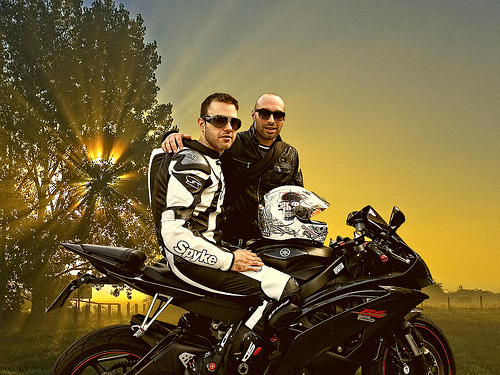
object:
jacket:
[138, 133, 241, 274]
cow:
[452, 292, 475, 309]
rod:
[443, 295, 453, 311]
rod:
[474, 293, 488, 312]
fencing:
[418, 292, 499, 313]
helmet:
[248, 178, 336, 254]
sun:
[62, 139, 143, 216]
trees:
[450, 277, 499, 296]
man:
[149, 81, 317, 288]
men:
[136, 83, 327, 375]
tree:
[3, 0, 188, 323]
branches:
[23, 156, 58, 218]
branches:
[7, 48, 44, 123]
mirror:
[381, 202, 412, 235]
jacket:
[156, 118, 310, 246]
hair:
[192, 89, 241, 123]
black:
[234, 221, 249, 233]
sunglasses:
[248, 104, 289, 122]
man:
[135, 88, 308, 375]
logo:
[347, 304, 389, 326]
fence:
[61, 294, 161, 331]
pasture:
[6, 320, 56, 363]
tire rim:
[355, 309, 460, 375]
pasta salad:
[31, 200, 458, 374]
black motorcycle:
[35, 198, 467, 374]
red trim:
[357, 310, 461, 374]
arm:
[147, 155, 230, 274]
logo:
[277, 246, 294, 261]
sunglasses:
[195, 109, 246, 135]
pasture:
[460, 303, 498, 372]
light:
[384, 204, 408, 233]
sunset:
[3, 1, 499, 276]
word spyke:
[162, 236, 221, 267]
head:
[192, 88, 245, 153]